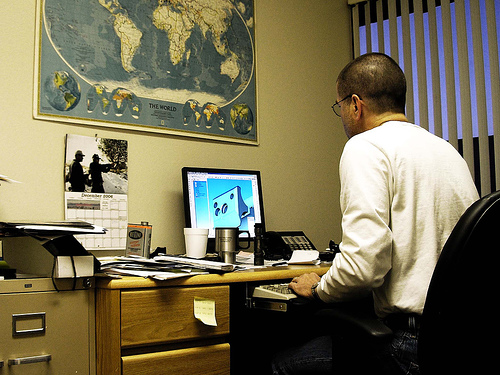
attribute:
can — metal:
[127, 219, 178, 250]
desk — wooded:
[102, 247, 277, 374]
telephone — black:
[263, 230, 319, 264]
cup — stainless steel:
[205, 221, 256, 268]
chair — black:
[415, 188, 499, 374]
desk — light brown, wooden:
[95, 241, 377, 373]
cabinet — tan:
[1, 277, 98, 374]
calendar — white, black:
[61, 130, 130, 253]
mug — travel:
[208, 215, 263, 281]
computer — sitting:
[175, 158, 345, 303]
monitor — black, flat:
[180, 162, 267, 239]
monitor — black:
[181, 167, 265, 242]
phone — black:
[262, 222, 319, 262]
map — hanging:
[33, 0, 259, 145]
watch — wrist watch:
[308, 280, 324, 305]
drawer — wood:
[119, 286, 231, 346]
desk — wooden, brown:
[97, 249, 344, 374]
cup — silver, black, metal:
[210, 216, 255, 271]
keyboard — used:
[249, 276, 300, 299]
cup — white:
[178, 221, 210, 261]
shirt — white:
[320, 120, 480, 317]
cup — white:
[182, 217, 212, 260]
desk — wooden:
[87, 255, 362, 374]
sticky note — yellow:
[190, 299, 226, 325]